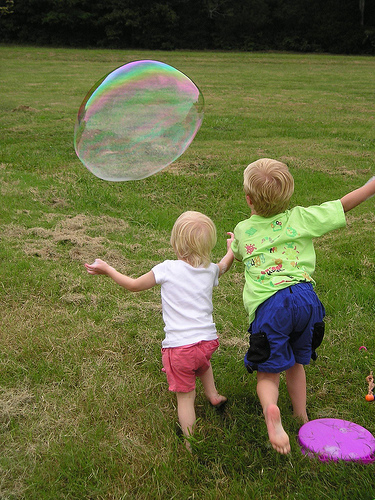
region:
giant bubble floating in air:
[64, 33, 219, 206]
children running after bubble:
[35, 48, 357, 401]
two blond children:
[154, 147, 344, 427]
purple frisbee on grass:
[290, 401, 374, 484]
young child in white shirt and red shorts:
[97, 194, 240, 434]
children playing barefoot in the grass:
[130, 304, 332, 479]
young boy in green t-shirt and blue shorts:
[228, 150, 353, 456]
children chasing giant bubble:
[35, 39, 349, 335]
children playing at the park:
[62, 64, 350, 421]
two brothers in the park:
[144, 144, 357, 418]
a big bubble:
[36, 51, 255, 217]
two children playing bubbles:
[66, 63, 334, 339]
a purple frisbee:
[294, 405, 373, 485]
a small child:
[83, 188, 255, 414]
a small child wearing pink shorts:
[120, 199, 265, 415]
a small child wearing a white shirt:
[117, 208, 251, 414]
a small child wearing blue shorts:
[204, 128, 346, 355]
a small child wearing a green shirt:
[213, 137, 346, 378]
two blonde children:
[120, 159, 362, 313]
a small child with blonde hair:
[136, 192, 280, 416]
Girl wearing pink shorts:
[85, 209, 233, 452]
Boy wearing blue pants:
[230, 157, 374, 454]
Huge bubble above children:
[71, 57, 205, 185]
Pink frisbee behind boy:
[298, 415, 373, 464]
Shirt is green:
[227, 199, 345, 325]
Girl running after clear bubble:
[83, 206, 233, 447]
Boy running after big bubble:
[226, 158, 372, 458]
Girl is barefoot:
[82, 206, 230, 450]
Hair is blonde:
[243, 156, 293, 214]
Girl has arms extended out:
[85, 209, 234, 456]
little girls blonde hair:
[148, 200, 244, 268]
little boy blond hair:
[218, 173, 317, 222]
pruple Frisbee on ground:
[297, 409, 366, 487]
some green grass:
[28, 317, 153, 477]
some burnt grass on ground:
[43, 188, 164, 281]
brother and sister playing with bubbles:
[106, 195, 372, 353]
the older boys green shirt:
[231, 219, 330, 318]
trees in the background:
[123, 0, 336, 50]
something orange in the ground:
[355, 347, 373, 396]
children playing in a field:
[83, 127, 371, 463]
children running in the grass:
[86, 158, 357, 457]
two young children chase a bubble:
[50, 59, 354, 459]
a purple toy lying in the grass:
[294, 412, 374, 481]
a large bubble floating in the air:
[65, 60, 204, 188]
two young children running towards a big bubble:
[97, 137, 356, 446]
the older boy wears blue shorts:
[232, 156, 358, 445]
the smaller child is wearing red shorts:
[100, 216, 235, 456]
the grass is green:
[26, 52, 373, 446]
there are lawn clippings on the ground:
[18, 157, 240, 498]